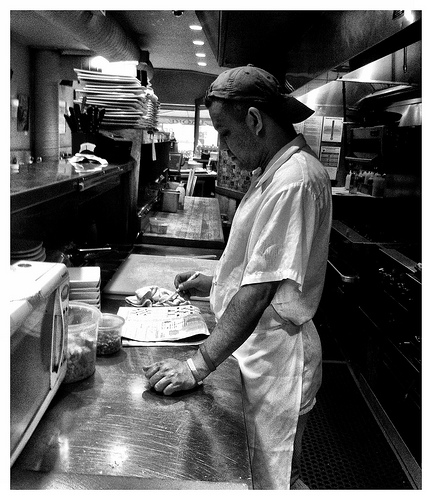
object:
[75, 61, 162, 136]
trays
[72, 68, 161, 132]
plates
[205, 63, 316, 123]
cap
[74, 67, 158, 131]
stack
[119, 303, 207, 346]
page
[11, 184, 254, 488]
counter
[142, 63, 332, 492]
worker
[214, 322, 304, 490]
apron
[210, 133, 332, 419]
shirt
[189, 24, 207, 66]
lighting fixtures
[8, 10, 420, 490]
kitchen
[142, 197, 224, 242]
table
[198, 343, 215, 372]
wrist band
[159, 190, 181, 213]
tin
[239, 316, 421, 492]
ground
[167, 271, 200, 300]
pen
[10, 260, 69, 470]
microwave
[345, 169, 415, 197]
bottles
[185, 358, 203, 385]
wrist bands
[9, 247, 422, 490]
down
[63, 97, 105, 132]
knives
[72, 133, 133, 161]
container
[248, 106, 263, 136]
ear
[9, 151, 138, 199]
shelf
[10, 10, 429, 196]
background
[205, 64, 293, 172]
head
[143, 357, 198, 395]
hand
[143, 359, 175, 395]
finger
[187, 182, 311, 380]
arm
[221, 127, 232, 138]
eye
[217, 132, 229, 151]
nose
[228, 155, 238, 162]
mouth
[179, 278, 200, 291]
thumb